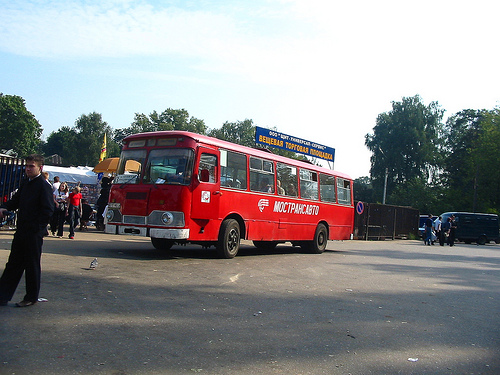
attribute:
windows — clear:
[219, 147, 338, 205]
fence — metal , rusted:
[363, 205, 418, 236]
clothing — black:
[3, 175, 53, 298]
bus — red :
[101, 127, 357, 264]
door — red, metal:
[187, 143, 227, 228]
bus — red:
[146, 132, 371, 264]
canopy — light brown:
[369, 210, 471, 258]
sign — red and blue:
[354, 199, 367, 215]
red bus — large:
[90, 123, 407, 239]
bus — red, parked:
[102, 132, 355, 247]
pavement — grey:
[1, 224, 498, 372]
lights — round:
[98, 190, 202, 242]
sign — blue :
[255, 123, 337, 163]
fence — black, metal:
[353, 203, 420, 239]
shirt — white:
[52, 189, 69, 209]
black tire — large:
[201, 212, 313, 248]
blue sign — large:
[253, 127, 335, 166]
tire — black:
[309, 221, 326, 253]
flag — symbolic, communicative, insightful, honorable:
[93, 131, 106, 166]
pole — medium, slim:
[103, 128, 110, 157]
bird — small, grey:
[82, 255, 101, 272]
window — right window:
[197, 136, 272, 203]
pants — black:
[3, 232, 42, 297]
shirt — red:
[71, 191, 79, 206]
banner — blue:
[244, 120, 340, 176]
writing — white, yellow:
[258, 130, 333, 165]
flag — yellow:
[91, 136, 114, 168]